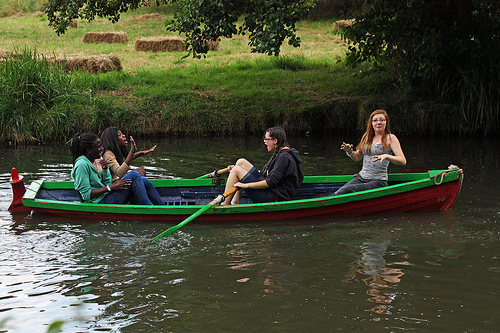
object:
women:
[330, 109, 407, 196]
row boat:
[21, 164, 466, 221]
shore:
[4, 63, 497, 137]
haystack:
[60, 54, 123, 73]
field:
[0, 0, 393, 129]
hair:
[356, 109, 392, 157]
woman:
[219, 126, 304, 205]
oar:
[150, 186, 238, 243]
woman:
[91, 126, 157, 183]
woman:
[67, 133, 163, 206]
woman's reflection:
[356, 237, 411, 316]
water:
[0, 148, 500, 332]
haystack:
[82, 31, 129, 43]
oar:
[192, 165, 233, 180]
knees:
[231, 165, 240, 175]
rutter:
[8, 167, 30, 211]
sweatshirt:
[71, 155, 113, 204]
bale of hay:
[134, 34, 187, 53]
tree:
[162, 0, 241, 62]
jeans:
[97, 171, 165, 206]